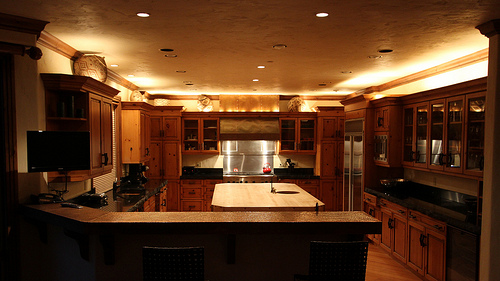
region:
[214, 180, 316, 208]
a brown table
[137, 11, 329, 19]
two ceiling lamps on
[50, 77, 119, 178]
a big cabinet on the wall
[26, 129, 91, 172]
a TV monitor display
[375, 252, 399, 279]
a wooden tile floor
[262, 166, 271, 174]
a red object in the distance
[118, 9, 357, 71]
a large white ceiling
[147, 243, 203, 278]
a chair behind the counter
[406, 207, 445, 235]
a wooden brown drawer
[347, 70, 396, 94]
the light on the ceiling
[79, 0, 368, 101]
ceiling of the room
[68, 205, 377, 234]
counter in the kitchen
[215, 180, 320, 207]
island in the kitchen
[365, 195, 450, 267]
cabinets in the kitchen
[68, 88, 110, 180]
cabinets on the wall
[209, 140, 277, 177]
stove in the kitchen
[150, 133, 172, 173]
the cabinets are wood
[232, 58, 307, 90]
lights on the ceiling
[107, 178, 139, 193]
sink in the kitchen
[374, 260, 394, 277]
the floor is wood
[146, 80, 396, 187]
a kitchen with cabinets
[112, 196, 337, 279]
a kitchen with chairs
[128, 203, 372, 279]
a kithen with bar stools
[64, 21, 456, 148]
lights above teh cabinet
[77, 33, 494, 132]
lights above the kitchen cabinets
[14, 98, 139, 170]
a tv above the counter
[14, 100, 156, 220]
a tv in the kitchen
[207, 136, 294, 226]
a silver kitchen stove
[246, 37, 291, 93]
Pot lights in ceiling of kitchen.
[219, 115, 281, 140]
Silver hood over stove.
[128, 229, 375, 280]
Chairs pushed up to kitchen counter.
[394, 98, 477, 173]
Glass covered cabinet doors.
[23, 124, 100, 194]
Computer monitor sitting on counter.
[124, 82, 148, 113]
Vase sitting on top of cabinet.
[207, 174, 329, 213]
Wood covered kitchen island.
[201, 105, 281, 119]
Lights on top of kitchen cabinets.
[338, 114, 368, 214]
Refrigerator sitting in kitchen.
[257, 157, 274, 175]
Red tea kettle on stove top.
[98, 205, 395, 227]
the countertop is empty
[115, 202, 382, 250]
the countertop is empty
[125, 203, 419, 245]
the countertop is empty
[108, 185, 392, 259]
the countertop is empty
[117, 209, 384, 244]
the countertop is empty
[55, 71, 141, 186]
the cabinet is closed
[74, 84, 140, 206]
the cabinet is closed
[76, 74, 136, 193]
the cabinet is closed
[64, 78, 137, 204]
the cabinet is closed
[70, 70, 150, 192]
the cabinet is closed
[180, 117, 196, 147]
glass cabinet face in the kitchen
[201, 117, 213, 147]
glass cabinet face in the kitchen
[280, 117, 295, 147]
glass cabinet face in the kitchen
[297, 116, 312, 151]
glass cabinet face in the kitchen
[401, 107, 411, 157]
glass cabinet face in the kitchen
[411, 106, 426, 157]
glass cabinet face in the kitchen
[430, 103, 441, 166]
glass cabinet face in the kitchen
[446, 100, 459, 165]
glass cabinet face in the kitchen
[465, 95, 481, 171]
glass cabinet face in the kitchen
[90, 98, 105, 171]
wooden cabinet face in the kitchen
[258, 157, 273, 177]
a red teapot on a stove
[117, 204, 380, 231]
a long counter top